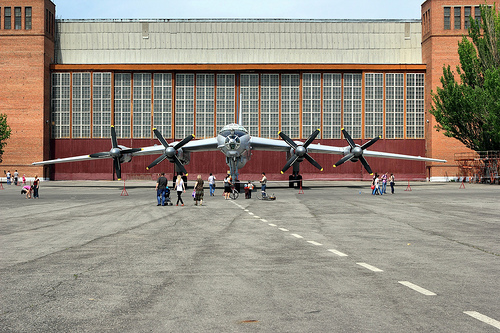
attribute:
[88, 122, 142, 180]
propeller — large, silver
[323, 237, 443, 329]
lines — white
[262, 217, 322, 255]
dash — white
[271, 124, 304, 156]
propeller — black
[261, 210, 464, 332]
lines — white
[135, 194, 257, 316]
lines — dark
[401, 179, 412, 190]
safety triangle — orange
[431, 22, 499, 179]
tree — tall, green, leafy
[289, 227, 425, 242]
dash — white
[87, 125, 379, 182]
propellers — black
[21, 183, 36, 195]
shirt — pink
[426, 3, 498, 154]
leaves — green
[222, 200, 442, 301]
dash — white